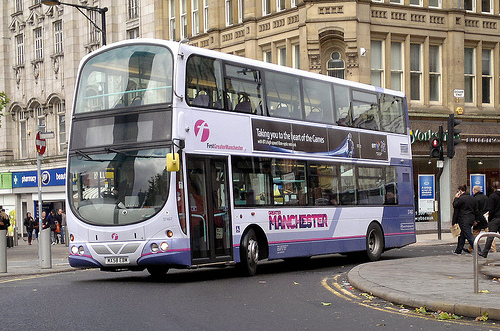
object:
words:
[256, 128, 324, 146]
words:
[265, 208, 326, 228]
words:
[407, 126, 460, 143]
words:
[417, 173, 436, 212]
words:
[22, 174, 36, 183]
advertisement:
[194, 119, 244, 151]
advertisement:
[13, 171, 66, 186]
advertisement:
[251, 118, 388, 161]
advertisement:
[268, 210, 328, 230]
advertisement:
[470, 174, 487, 196]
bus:
[66, 38, 416, 278]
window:
[230, 155, 271, 208]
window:
[302, 79, 334, 124]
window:
[265, 70, 304, 120]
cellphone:
[455, 189, 465, 198]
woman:
[451, 184, 483, 258]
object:
[80, 85, 172, 98]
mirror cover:
[166, 152, 180, 171]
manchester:
[268, 210, 328, 230]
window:
[366, 92, 407, 135]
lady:
[452, 184, 483, 258]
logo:
[194, 119, 210, 142]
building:
[0, 0, 500, 228]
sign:
[250, 118, 389, 161]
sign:
[35, 131, 45, 156]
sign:
[470, 174, 486, 198]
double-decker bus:
[65, 38, 415, 280]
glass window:
[221, 62, 266, 116]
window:
[332, 83, 354, 128]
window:
[352, 87, 382, 131]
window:
[272, 158, 311, 206]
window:
[305, 161, 340, 206]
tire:
[234, 229, 261, 276]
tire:
[363, 221, 383, 261]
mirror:
[166, 153, 180, 172]